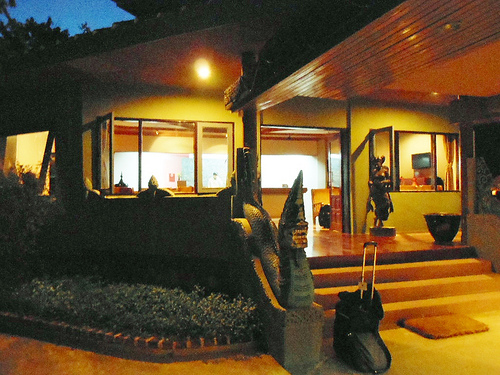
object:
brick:
[126, 337, 141, 350]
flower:
[222, 293, 234, 301]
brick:
[194, 339, 204, 349]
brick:
[178, 340, 192, 352]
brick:
[162, 339, 176, 351]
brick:
[118, 333, 126, 345]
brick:
[209, 337, 218, 347]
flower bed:
[0, 273, 265, 345]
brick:
[148, 337, 167, 351]